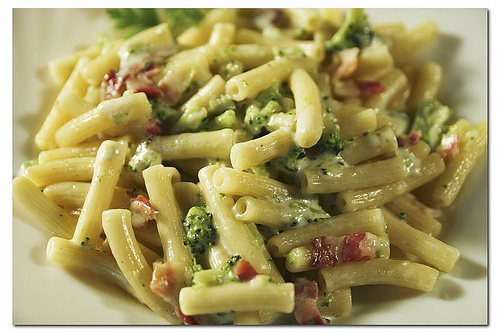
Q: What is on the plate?
A: Food.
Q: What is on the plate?
A: Food.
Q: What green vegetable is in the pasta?
A: Broccoli.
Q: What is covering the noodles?
A: Sauce.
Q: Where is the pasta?
A: On the plate.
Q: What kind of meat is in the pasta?
A: Bacon.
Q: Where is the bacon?
A: In the pasta.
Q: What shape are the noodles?
A: Small penne.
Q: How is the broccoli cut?
A: In small pieces.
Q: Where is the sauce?
A: On the pasta.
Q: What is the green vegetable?
A: Broccoli.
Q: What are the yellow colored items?
A: Pasta.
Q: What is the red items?
A: Bacon pieces.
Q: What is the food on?
A: Plate.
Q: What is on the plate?
A: Pasta.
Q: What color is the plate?
A: White.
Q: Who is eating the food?
A: A man.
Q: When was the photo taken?
A: Day time.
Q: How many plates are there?
A: One.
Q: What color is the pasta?
A: Tan.